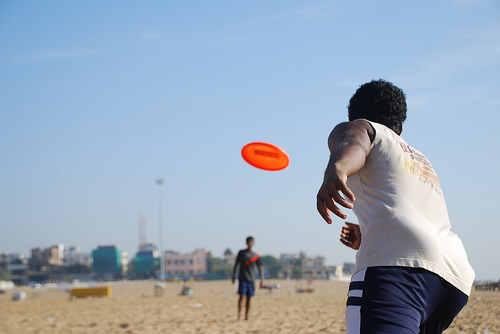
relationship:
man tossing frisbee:
[315, 76, 479, 333] [229, 115, 316, 187]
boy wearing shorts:
[227, 232, 267, 325] [230, 273, 258, 299]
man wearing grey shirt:
[315, 76, 479, 333] [327, 115, 490, 298]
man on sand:
[315, 76, 479, 333] [202, 308, 272, 332]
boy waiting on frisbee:
[230, 235, 265, 324] [239, 135, 292, 175]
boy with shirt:
[230, 235, 265, 324] [233, 246, 263, 281]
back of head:
[344, 66, 427, 151] [353, 77, 403, 128]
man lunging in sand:
[315, 76, 479, 333] [105, 261, 206, 327]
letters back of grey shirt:
[393, 142, 440, 191] [349, 117, 475, 297]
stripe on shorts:
[348, 279, 364, 289] [344, 264, 469, 332]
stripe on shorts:
[345, 295, 365, 305] [344, 264, 469, 332]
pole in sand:
[152, 176, 167, 283] [1, 279, 498, 332]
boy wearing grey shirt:
[230, 235, 265, 324] [227, 247, 266, 280]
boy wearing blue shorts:
[230, 235, 265, 324] [233, 279, 255, 295]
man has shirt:
[315, 76, 479, 333] [297, 92, 499, 261]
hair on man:
[343, 76, 409, 128] [315, 76, 479, 333]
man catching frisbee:
[315, 76, 479, 333] [237, 137, 292, 172]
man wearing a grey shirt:
[281, 67, 461, 319] [349, 117, 475, 297]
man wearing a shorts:
[281, 67, 461, 319] [344, 264, 469, 332]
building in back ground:
[31, 246, 41, 272] [1, 1, 498, 331]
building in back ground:
[0, 243, 89, 289] [1, 1, 498, 331]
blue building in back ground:
[91, 244, 124, 283] [1, 1, 498, 331]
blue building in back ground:
[127, 241, 162, 281] [1, 1, 498, 331]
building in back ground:
[161, 247, 209, 281] [1, 1, 498, 331]